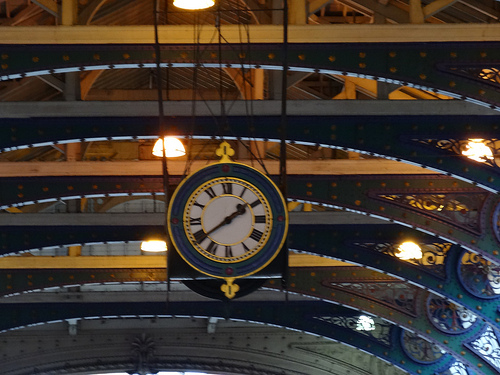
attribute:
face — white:
[186, 176, 271, 260]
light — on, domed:
[170, 0, 213, 11]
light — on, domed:
[153, 134, 187, 161]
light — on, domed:
[140, 237, 168, 255]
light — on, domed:
[354, 314, 377, 336]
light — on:
[395, 240, 424, 261]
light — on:
[461, 136, 499, 169]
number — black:
[220, 180, 234, 200]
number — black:
[250, 195, 263, 210]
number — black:
[221, 241, 234, 261]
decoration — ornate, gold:
[216, 141, 234, 164]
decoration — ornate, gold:
[215, 277, 244, 300]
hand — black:
[229, 202, 251, 224]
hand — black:
[190, 222, 230, 248]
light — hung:
[394, 237, 424, 262]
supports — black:
[152, 0, 171, 292]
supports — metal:
[278, 0, 291, 290]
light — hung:
[461, 135, 495, 162]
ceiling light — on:
[138, 232, 170, 257]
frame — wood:
[210, 67, 270, 109]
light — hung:
[153, 134, 185, 159]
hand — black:
[203, 199, 250, 241]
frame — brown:
[223, 79, 300, 122]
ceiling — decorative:
[298, 163, 478, 278]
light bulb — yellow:
[165, 145, 180, 158]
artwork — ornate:
[129, 331, 155, 359]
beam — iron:
[2, 314, 405, 374]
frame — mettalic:
[287, 97, 432, 179]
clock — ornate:
[162, 155, 292, 283]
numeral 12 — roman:
[218, 180, 236, 198]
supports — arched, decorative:
[0, 42, 500, 374]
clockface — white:
[185, 177, 273, 260]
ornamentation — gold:
[212, 138, 238, 161]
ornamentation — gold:
[219, 279, 241, 297]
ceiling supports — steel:
[287, 275, 464, 343]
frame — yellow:
[161, 160, 292, 282]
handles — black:
[197, 203, 250, 243]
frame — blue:
[320, 120, 449, 162]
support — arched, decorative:
[2, 100, 483, 192]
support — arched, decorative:
[0, 210, 483, 324]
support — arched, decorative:
[2, 295, 460, 373]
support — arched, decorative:
[2, 320, 409, 372]